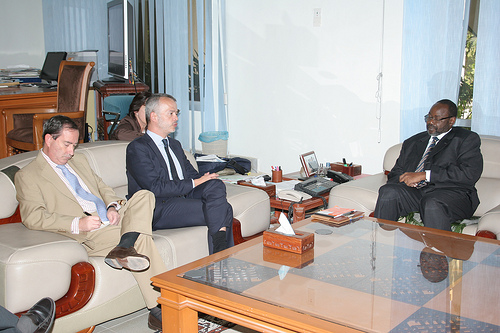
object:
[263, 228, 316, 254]
box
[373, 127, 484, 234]
suit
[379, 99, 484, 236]
man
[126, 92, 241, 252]
man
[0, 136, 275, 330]
couch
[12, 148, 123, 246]
jacket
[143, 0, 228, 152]
blinds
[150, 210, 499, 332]
square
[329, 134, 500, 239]
chair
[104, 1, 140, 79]
tv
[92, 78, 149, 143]
stand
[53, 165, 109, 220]
tie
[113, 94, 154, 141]
lady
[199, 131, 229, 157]
small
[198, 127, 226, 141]
blue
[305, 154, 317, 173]
picture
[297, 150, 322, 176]
frame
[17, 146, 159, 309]
suit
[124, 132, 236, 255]
suit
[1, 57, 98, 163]
chair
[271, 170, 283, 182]
pot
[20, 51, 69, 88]
computer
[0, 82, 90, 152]
desk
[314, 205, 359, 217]
notepad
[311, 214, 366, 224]
planner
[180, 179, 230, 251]
leg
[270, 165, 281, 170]
pens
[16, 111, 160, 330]
man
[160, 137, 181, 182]
tie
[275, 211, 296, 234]
tissue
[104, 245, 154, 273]
shoe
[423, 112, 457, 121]
pair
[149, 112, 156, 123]
ear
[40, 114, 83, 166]
head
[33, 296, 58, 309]
tip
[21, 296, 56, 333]
shoe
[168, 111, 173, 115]
eye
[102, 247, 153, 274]
foot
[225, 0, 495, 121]
window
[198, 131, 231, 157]
trash can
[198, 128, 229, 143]
garbage bag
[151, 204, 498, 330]
coffee table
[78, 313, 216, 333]
floor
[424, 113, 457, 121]
glasses